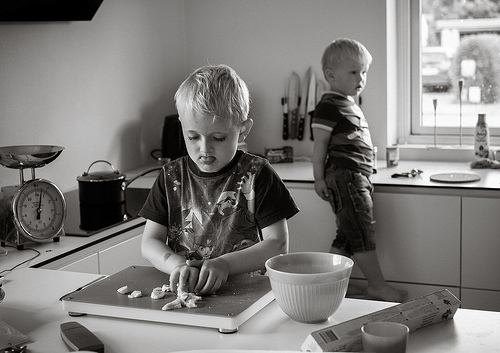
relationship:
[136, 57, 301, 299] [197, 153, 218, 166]
boy has tongue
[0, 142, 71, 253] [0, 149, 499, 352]
scale on counter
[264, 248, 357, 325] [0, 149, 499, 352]
bowl on counter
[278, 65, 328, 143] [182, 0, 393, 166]
knives on wall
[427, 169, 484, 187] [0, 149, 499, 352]
plate on counter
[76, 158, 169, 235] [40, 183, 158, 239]
pot on stove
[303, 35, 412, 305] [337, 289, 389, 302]
boy on stool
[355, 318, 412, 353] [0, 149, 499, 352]
cup on counter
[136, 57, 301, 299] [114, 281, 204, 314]
boy with food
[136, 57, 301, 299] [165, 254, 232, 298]
child has hands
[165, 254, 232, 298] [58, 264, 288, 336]
hands on chopping board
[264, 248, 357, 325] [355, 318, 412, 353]
bowl next to cup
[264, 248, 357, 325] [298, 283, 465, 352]
bowl next to box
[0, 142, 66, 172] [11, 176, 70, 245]
bowl over dial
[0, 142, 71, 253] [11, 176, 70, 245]
scale has dial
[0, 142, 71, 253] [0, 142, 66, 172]
scale has bowl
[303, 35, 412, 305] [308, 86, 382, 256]
child has clothes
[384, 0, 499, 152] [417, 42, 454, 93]
window shows car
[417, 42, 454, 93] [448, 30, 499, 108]
car next to hedges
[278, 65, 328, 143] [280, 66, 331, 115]
knives have blades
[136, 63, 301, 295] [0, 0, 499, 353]
boy in kitchen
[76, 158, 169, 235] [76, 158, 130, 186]
pot has lid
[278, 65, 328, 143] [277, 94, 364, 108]
knives on rack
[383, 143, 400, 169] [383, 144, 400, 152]
jar has lid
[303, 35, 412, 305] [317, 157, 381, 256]
child wearing shorts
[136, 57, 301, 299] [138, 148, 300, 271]
child wearing t-shirt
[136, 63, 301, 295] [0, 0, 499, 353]
boy in room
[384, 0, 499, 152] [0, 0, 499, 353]
window in room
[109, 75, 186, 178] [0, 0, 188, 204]
shadow on wall